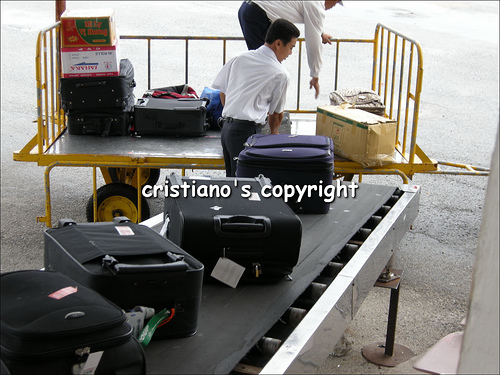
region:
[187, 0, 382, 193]
Two men handling luggage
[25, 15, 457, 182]
Luggage on a cart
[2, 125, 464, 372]
Luggage on a conveyor belt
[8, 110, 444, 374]
A conveyor belt used for luggage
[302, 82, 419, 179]
A cardboard box on a car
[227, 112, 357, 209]
One blue suitcase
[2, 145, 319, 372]
Three black suitcases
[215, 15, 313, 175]
Man wearing white shirt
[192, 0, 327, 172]
Man wearing black pants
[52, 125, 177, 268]
Wheels on a luggage cart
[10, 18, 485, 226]
yellow painted metal luggage cart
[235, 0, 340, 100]
person on luggage cart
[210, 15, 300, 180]
man next to luggage cart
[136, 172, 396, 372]
black rubber belt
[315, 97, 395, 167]
long cardboard box on luggage cart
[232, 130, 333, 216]
navy blue luggage on belt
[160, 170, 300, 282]
black luggage on belt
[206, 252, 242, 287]
white name tag on luggage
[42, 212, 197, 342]
black luggage on belt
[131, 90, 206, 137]
black luggage on cart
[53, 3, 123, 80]
Two cardboard boxes stacked on top of each other.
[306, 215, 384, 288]
Conveyor belt used for carrying luggage.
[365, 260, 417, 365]
Rusted, steel component for support.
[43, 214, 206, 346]
Black suitcase traveling on the belt.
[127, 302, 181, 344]
Several luggage tags showing destination.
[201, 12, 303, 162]
Man lifting the luggage and moving it.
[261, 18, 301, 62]
Man with black hair.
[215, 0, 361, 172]
Two men working together at the airport.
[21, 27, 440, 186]
Large yellow cart used to transport the luggage from one location to another.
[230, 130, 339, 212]
Blue suitcase at the end of the belt.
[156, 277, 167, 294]
the luggage is black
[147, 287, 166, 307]
the luggage is black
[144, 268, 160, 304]
the luggage is black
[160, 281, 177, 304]
the luggage is black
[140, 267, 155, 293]
the luggage is black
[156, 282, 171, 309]
the luggage is black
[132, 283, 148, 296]
the luggage is black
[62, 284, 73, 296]
the tag is red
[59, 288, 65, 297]
the tag is red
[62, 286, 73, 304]
the tag is red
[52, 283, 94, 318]
the tag is red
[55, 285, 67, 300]
the tag is red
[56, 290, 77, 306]
the tag is red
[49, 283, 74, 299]
the tag is red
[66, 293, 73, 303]
the tag is red